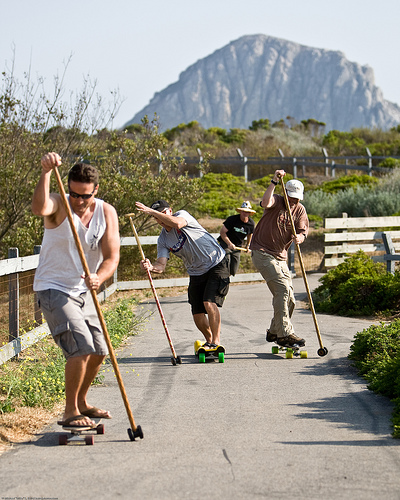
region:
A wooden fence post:
[4, 239, 25, 371]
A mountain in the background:
[112, 31, 398, 140]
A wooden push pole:
[123, 212, 183, 366]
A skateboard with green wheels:
[191, 340, 241, 376]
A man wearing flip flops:
[26, 153, 134, 476]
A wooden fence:
[320, 210, 397, 291]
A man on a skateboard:
[252, 170, 335, 363]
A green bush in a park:
[313, 251, 395, 324]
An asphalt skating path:
[0, 293, 397, 498]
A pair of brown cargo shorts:
[171, 250, 244, 358]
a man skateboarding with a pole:
[29, 150, 146, 450]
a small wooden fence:
[0, 229, 48, 361]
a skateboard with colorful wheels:
[192, 337, 220, 361]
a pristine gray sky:
[2, 5, 398, 115]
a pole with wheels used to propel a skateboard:
[120, 212, 180, 364]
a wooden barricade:
[321, 217, 397, 261]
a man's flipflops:
[58, 404, 111, 428]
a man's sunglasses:
[68, 186, 100, 198]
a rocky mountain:
[122, 32, 394, 125]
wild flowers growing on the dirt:
[6, 314, 62, 411]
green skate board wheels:
[197, 348, 224, 365]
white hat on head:
[283, 174, 305, 201]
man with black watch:
[248, 167, 311, 348]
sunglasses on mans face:
[65, 160, 101, 213]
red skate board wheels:
[54, 432, 95, 446]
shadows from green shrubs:
[274, 355, 398, 451]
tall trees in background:
[121, 113, 326, 150]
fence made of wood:
[323, 211, 399, 273]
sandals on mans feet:
[55, 404, 113, 429]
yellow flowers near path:
[2, 315, 67, 411]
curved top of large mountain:
[236, 27, 281, 51]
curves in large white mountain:
[226, 85, 257, 109]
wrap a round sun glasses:
[69, 188, 95, 197]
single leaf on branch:
[0, 71, 12, 80]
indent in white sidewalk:
[356, 408, 384, 427]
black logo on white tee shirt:
[82, 231, 106, 248]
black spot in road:
[213, 444, 246, 467]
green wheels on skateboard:
[200, 354, 231, 365]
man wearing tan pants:
[249, 243, 311, 335]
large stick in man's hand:
[120, 212, 198, 371]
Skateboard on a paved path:
[54, 403, 127, 467]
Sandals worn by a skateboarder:
[54, 399, 123, 439]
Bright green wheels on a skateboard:
[192, 351, 236, 365]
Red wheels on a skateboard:
[52, 428, 102, 444]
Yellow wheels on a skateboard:
[272, 336, 325, 366]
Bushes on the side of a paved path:
[355, 324, 397, 376]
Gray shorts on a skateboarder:
[34, 289, 114, 362]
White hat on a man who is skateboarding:
[278, 176, 319, 206]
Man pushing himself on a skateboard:
[124, 202, 246, 360]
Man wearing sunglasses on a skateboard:
[36, 151, 137, 420]